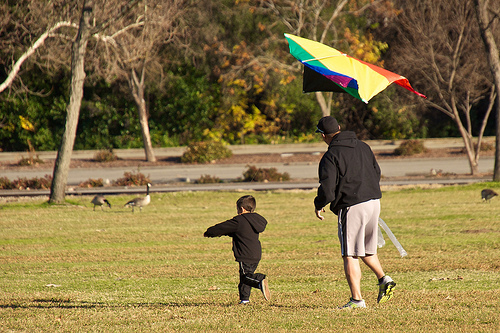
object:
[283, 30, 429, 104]
kite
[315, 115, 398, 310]
man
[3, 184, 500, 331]
grass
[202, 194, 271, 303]
little boy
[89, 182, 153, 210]
geese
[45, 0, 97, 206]
tree trunk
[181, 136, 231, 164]
bush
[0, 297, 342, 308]
shadow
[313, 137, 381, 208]
hoodie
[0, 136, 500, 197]
street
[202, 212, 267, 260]
sweatshirt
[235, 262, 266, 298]
pants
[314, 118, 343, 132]
hat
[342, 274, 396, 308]
sneakers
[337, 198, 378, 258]
shorts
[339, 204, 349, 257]
line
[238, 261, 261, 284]
line